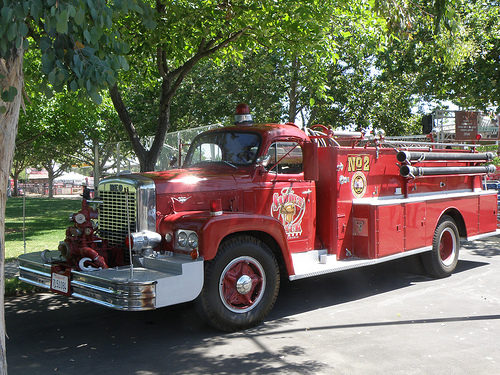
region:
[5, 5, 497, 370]
A fire engine is parked.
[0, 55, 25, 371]
The trunk of a tree.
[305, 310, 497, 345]
A shadow on the road.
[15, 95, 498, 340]
The fire engine is red.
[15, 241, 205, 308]
A bumper on the front of the fire engine.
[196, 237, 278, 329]
The front tire on the fire engine.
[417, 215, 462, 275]
The back tire on the fire engine.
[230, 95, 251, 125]
A siren on top of the fire engine.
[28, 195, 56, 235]
Green grass in the distance.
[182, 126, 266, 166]
The windshield on the fire engine.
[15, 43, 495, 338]
shiny red fire truck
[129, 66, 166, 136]
green leafy tree branches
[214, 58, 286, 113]
green leafy tree branches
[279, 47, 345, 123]
green leafy tree branches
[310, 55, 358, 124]
green leafy tree branches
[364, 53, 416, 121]
green leafy tree branches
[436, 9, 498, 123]
green leafy tree branches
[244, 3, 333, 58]
green leafy tree branches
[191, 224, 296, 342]
front wheel of firetruck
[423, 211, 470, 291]
back wheel of firetruck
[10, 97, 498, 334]
a red and sliver fire truck parked at the curb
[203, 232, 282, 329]
the truck's front tire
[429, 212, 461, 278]
the truck's back tire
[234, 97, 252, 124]
the truck's light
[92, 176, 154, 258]
the truck's shiny silver grill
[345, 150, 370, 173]
the truck has No2 painted on it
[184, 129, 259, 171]
the truck's windshield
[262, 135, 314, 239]
the truck's driver's side door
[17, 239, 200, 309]
the truck's bumper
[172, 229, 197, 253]
the truck's headlight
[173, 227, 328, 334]
the wheels on a truck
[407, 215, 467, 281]
the back wheel of a truck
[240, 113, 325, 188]
the side window of a truck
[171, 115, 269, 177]
the windshield of a truck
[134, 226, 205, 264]
the headlight of a truck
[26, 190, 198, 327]
the bumper of a truck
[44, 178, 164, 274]
the grill of a truck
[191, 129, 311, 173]
the windshield wiper of a truck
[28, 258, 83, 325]
the license plate of a truck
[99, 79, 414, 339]
a big red truck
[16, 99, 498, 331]
red fire truck parked on the street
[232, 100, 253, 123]
red light on top of truck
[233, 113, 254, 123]
silver ring below light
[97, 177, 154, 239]
metal grill attached to the fire truck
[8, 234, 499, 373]
paved street under fire truck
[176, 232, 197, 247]
headlight is off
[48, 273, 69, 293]
white license plate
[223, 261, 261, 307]
red hubcap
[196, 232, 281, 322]
black rubber tire under fire truck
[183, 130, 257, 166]
clear windshield